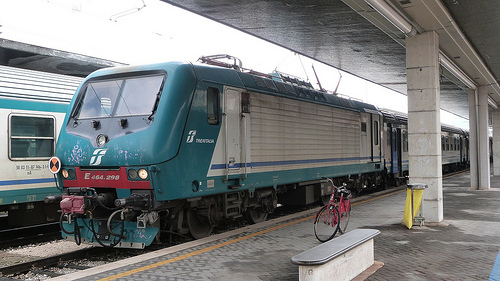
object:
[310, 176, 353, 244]
bicycle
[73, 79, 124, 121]
windshield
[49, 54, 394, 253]
car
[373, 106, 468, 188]
passenger car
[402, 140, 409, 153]
passenger window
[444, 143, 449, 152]
passenger window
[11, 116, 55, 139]
window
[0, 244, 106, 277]
railing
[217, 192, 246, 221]
ladder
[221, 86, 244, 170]
door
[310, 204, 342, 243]
wheel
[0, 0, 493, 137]
sky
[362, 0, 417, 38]
lighting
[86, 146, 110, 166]
sign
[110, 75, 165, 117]
windsheild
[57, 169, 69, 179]
headlight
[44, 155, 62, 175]
sign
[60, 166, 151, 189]
paint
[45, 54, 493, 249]
train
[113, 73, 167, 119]
window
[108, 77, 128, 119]
bar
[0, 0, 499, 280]
train station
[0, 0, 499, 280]
scene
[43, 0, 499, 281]
platform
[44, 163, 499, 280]
cement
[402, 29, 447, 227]
column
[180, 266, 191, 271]
cobblestone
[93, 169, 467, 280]
line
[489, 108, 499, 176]
columns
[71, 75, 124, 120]
windows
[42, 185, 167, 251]
engine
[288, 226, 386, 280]
bench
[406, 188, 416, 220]
pole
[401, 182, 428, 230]
bag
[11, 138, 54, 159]
window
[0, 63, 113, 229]
train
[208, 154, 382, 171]
line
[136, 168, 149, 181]
head lights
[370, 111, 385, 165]
door